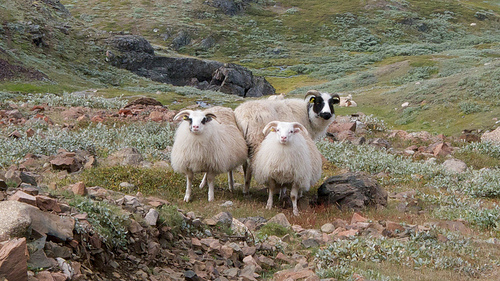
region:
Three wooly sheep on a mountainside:
[171, 88, 338, 215]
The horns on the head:
[300, 88, 342, 100]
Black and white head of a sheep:
[313, 93, 335, 120]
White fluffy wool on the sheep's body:
[249, 133, 322, 190]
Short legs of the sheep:
[265, 183, 300, 215]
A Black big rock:
[105, 33, 276, 97]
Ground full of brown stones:
[0, 98, 496, 278]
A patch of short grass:
[262, 74, 324, 94]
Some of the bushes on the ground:
[320, 140, 499, 278]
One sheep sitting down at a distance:
[339, 94, 355, 106]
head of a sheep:
[305, 71, 346, 127]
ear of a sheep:
[305, 85, 320, 98]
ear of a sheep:
[325, 93, 351, 107]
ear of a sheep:
[263, 117, 285, 133]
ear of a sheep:
[294, 120, 308, 137]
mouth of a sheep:
[275, 132, 294, 146]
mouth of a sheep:
[188, 116, 211, 132]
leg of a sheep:
[172, 167, 204, 222]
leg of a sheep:
[202, 164, 226, 207]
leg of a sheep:
[260, 174, 290, 204]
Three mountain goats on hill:
[159, 88, 353, 213]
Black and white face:
[307, 90, 339, 118]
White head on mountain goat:
[264, 120, 306, 145]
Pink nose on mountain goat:
[192, 124, 199, 131]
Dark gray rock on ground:
[323, 171, 386, 210]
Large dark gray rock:
[111, 34, 268, 95]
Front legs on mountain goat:
[181, 173, 216, 203]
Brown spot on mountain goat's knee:
[290, 193, 298, 203]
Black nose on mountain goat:
[322, 111, 332, 117]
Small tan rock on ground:
[72, 178, 90, 194]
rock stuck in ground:
[1, 237, 35, 279]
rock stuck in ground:
[30, 268, 67, 279]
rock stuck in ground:
[189, 260, 213, 272]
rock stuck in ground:
[234, 258, 255, 278]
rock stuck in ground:
[141, 208, 160, 228]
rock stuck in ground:
[190, 234, 204, 251]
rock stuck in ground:
[329, 160, 381, 214]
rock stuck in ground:
[51, 142, 85, 180]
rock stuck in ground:
[426, 135, 453, 162]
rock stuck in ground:
[150, 99, 178, 129]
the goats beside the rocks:
[162, 79, 345, 222]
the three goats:
[161, 77, 354, 211]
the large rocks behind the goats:
[116, 32, 262, 98]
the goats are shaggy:
[173, 65, 364, 228]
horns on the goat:
[174, 104, 224, 118]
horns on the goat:
[262, 118, 307, 130]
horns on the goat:
[306, 87, 340, 102]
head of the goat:
[171, 103, 218, 140]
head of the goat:
[260, 118, 307, 145]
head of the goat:
[311, 83, 346, 119]